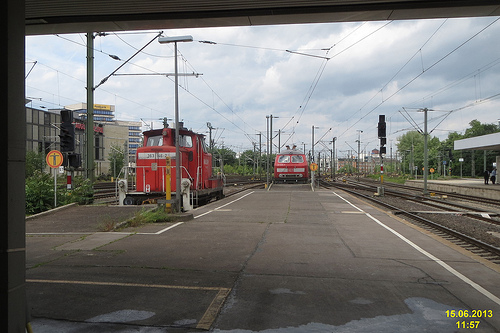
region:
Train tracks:
[327, 158, 497, 268]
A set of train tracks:
[326, 156, 496, 258]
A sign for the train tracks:
[41, 148, 69, 205]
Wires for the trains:
[49, 33, 491, 142]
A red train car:
[131, 113, 218, 198]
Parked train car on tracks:
[124, 111, 229, 204]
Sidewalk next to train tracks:
[35, 186, 497, 331]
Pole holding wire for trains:
[393, 87, 447, 194]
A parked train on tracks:
[266, 143, 311, 185]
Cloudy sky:
[28, 33, 483, 143]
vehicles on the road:
[116, 99, 334, 227]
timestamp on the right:
[436, 307, 496, 332]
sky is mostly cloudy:
[328, 66, 425, 126]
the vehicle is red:
[271, 158, 306, 184]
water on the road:
[366, 300, 428, 332]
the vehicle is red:
[177, 153, 223, 201]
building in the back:
[65, 100, 110, 127]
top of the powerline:
[413, 104, 444, 116]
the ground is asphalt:
[262, 223, 334, 262]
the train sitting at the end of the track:
[134, 128, 222, 203]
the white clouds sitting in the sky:
[38, 18, 498, 125]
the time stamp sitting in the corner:
[441, 306, 496, 328]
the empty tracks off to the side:
[331, 175, 499, 281]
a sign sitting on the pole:
[43, 149, 65, 205]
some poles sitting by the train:
[258, 112, 283, 154]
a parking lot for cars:
[41, 194, 491, 327]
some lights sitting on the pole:
[372, 117, 389, 149]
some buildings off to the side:
[28, 107, 144, 177]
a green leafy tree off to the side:
[403, 127, 442, 174]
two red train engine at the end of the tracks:
[123, 125, 307, 207]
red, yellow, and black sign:
[45, 149, 63, 209]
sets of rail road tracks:
[318, 170, 498, 267]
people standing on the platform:
[480, 167, 496, 188]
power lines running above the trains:
[23, 19, 493, 145]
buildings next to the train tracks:
[21, 102, 143, 204]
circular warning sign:
[42, 150, 64, 168]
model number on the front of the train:
[142, 151, 172, 160]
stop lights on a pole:
[57, 109, 83, 171]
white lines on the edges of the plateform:
[151, 182, 498, 329]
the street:
[268, 232, 312, 277]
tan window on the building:
[55, 112, 60, 124]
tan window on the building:
[46, 111, 54, 124]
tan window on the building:
[41, 110, 47, 122]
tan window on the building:
[37, 107, 42, 122]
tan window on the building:
[30, 105, 36, 120]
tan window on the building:
[25, 107, 31, 122]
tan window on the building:
[30, 122, 36, 137]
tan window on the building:
[37, 121, 43, 139]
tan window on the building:
[48, 125, 54, 141]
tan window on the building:
[53, 125, 62, 142]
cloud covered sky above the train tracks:
[29, 38, 499, 150]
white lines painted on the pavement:
[130, 192, 483, 331]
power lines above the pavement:
[60, 12, 497, 153]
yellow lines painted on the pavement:
[31, 262, 241, 323]